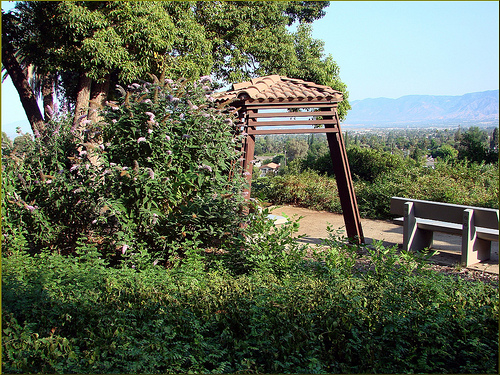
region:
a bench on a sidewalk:
[374, 163, 496, 298]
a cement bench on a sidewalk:
[357, 167, 497, 299]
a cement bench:
[390, 175, 496, 280]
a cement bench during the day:
[377, 168, 498, 267]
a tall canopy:
[179, 56, 372, 280]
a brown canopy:
[189, 50, 389, 280]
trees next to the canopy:
[9, 9, 371, 264]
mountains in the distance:
[304, 68, 499, 145]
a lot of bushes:
[22, 213, 489, 371]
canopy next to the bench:
[200, 43, 495, 264]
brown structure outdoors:
[179, 67, 365, 267]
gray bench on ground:
[385, 188, 488, 270]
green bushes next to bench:
[83, 263, 254, 361]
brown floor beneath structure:
[277, 208, 334, 295]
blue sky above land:
[332, 13, 471, 83]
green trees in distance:
[409, 120, 480, 157]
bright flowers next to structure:
[65, 86, 216, 218]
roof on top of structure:
[226, 62, 313, 119]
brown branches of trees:
[56, 76, 118, 171]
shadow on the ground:
[297, 223, 342, 271]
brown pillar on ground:
[310, 130, 385, 252]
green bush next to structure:
[78, 265, 334, 364]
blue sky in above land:
[363, 7, 473, 97]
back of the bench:
[383, 190, 498, 237]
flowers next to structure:
[64, 111, 226, 243]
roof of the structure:
[253, 65, 313, 104]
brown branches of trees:
[28, 85, 133, 142]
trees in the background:
[400, 124, 454, 151]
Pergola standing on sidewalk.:
[202, 75, 379, 274]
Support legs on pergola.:
[217, 130, 373, 250]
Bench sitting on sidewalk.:
[386, 186, 496, 267]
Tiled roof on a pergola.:
[201, 70, 349, 110]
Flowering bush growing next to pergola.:
[12, 75, 224, 276]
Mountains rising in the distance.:
[352, 77, 497, 147]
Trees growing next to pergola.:
[7, 2, 287, 187]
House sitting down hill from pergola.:
[255, 150, 300, 183]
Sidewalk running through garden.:
[265, 185, 426, 285]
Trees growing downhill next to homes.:
[426, 123, 499, 170]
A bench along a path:
[387, 188, 497, 264]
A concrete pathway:
[281, 197, 466, 267]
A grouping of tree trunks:
[23, 76, 124, 182]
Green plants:
[311, 246, 446, 356]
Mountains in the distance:
[377, 83, 488, 116]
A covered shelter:
[197, 67, 349, 224]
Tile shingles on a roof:
[225, 70, 337, 103]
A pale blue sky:
[340, 8, 468, 74]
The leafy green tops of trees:
[75, 5, 268, 50]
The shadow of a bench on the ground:
[349, 214, 472, 259]